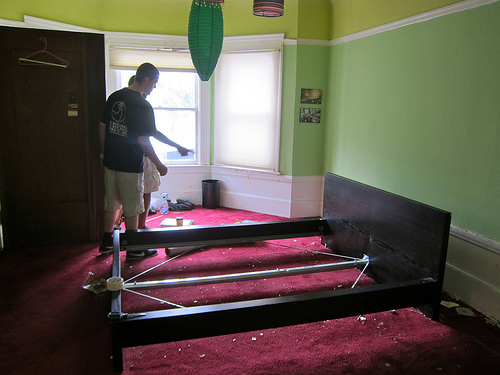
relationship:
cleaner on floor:
[82, 190, 486, 365] [147, 190, 175, 214]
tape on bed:
[106, 276, 124, 291] [106, 257, 429, 372]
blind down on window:
[218, 55, 273, 161] [211, 50, 276, 173]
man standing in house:
[98, 62, 169, 261] [0, 0, 500, 375]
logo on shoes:
[126, 251, 141, 261] [93, 236, 158, 262]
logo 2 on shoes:
[98, 242, 120, 254] [93, 236, 158, 262]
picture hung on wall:
[300, 87, 322, 103] [289, 18, 494, 231]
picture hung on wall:
[298, 107, 323, 123] [289, 18, 494, 231]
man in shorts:
[95, 60, 168, 257] [99, 166, 145, 219]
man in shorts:
[125, 74, 194, 265] [139, 156, 163, 195]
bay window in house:
[111, 53, 279, 170] [25, 10, 493, 360]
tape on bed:
[105, 276, 124, 292] [102, 171, 455, 375]